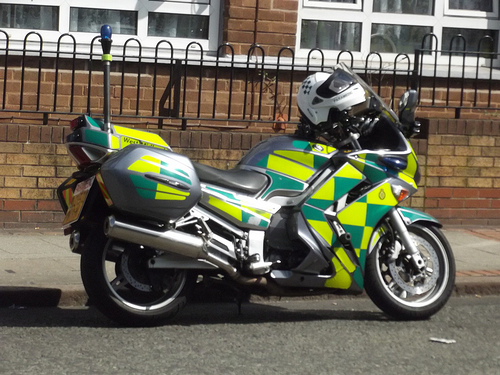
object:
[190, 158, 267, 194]
seat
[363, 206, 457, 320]
fronttire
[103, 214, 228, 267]
motorcycle exhaust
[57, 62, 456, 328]
bike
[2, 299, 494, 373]
street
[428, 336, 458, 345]
trash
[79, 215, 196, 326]
tire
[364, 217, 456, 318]
tire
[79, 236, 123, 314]
tire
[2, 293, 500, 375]
road